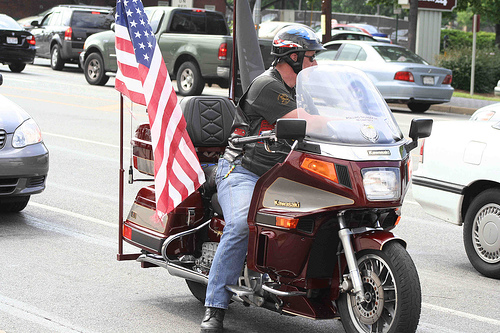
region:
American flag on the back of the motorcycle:
[111, 0, 208, 230]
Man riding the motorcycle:
[157, 11, 333, 326]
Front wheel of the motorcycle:
[315, 221, 450, 327]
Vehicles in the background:
[0, 0, 455, 110]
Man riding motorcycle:
[100, 0, 440, 330]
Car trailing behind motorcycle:
[0, 65, 70, 230]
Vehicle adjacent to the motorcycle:
[410, 95, 495, 285]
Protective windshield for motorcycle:
[290, 60, 406, 150]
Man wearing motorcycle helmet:
[264, 12, 323, 112]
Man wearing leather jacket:
[211, 59, 319, 189]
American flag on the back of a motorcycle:
[81, 1, 203, 218]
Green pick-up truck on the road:
[75, 6, 285, 83]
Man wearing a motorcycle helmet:
[271, 16, 323, 78]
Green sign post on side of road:
[408, 8, 443, 90]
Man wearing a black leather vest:
[219, 75, 315, 172]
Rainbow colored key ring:
[212, 158, 243, 185]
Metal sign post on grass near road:
[460, 8, 483, 100]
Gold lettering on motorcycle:
[270, 197, 307, 211]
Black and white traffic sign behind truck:
[169, 0, 193, 15]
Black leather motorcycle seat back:
[180, 94, 239, 146]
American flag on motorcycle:
[104, 0, 220, 236]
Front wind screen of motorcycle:
[279, 55, 412, 177]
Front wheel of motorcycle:
[316, 219, 431, 331]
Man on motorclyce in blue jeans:
[188, 139, 277, 331]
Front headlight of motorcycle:
[351, 158, 410, 208]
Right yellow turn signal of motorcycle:
[288, 145, 348, 196]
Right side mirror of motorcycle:
[262, 107, 320, 153]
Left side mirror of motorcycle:
[401, 113, 443, 150]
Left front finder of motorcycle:
[6, 108, 59, 207]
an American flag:
[111, 14, 176, 101]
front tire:
[397, 256, 422, 326]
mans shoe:
[203, 305, 223, 328]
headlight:
[363, 166, 401, 203]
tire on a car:
[479, 186, 494, 201]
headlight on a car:
[11, 122, 46, 146]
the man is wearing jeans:
[220, 210, 245, 265]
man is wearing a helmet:
[282, 20, 313, 45]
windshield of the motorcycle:
[300, 78, 397, 140]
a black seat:
[189, 96, 237, 141]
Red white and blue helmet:
[269, 11, 336, 93]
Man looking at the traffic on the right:
[194, 24, 359, 331]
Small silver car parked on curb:
[307, 31, 460, 113]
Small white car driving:
[405, 77, 499, 291]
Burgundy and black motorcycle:
[109, 31, 464, 331]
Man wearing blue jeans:
[187, 20, 339, 332]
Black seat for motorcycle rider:
[164, 86, 261, 150]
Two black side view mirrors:
[224, 117, 446, 162]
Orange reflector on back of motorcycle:
[114, 223, 139, 240]